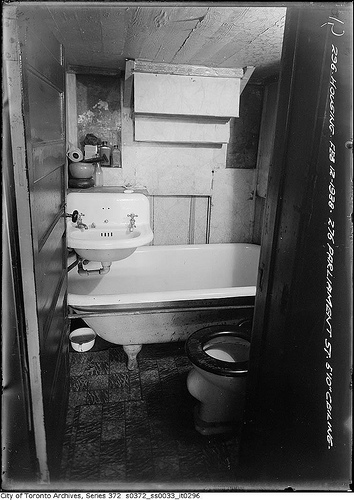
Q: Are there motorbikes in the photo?
A: No, there are no motorbikes.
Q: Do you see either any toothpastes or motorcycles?
A: No, there are no motorcycles or toothpastes.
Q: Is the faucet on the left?
A: Yes, the faucet is on the left of the image.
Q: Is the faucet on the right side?
A: No, the faucet is on the left of the image.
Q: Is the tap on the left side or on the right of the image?
A: The tap is on the left of the image.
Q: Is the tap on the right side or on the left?
A: The tap is on the left of the image.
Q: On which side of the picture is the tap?
A: The tap is on the left of the image.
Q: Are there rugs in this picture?
A: No, there are no rugs.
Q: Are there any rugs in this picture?
A: No, there are no rugs.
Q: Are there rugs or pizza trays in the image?
A: No, there are no rugs or pizza trays.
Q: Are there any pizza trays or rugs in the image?
A: No, there are no rugs or pizza trays.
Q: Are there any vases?
A: No, there are no vases.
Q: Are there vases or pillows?
A: No, there are no vases or pillows.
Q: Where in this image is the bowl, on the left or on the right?
A: The bowl is on the left of the image.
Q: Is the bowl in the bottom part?
A: Yes, the bowl is in the bottom of the image.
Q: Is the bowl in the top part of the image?
A: No, the bowl is in the bottom of the image.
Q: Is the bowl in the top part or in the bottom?
A: The bowl is in the bottom of the image.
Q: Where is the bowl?
A: The bowl is on the floor.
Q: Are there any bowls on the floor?
A: Yes, there is a bowl on the floor.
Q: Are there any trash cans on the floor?
A: No, there is a bowl on the floor.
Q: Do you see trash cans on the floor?
A: No, there is a bowl on the floor.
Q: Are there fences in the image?
A: No, there are no fences.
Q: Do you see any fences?
A: No, there are no fences.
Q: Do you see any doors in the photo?
A: Yes, there is a door.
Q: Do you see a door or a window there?
A: Yes, there is a door.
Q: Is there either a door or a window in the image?
A: Yes, there is a door.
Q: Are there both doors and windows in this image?
A: No, there is a door but no windows.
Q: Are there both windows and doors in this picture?
A: No, there is a door but no windows.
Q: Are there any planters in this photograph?
A: No, there are no planters.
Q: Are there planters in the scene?
A: No, there are no planters.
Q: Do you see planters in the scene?
A: No, there are no planters.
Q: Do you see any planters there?
A: No, there are no planters.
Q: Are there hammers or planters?
A: No, there are no planters or hammers.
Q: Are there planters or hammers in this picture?
A: No, there are no planters or hammers.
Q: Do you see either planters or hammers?
A: No, there are no planters or hammers.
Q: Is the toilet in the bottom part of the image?
A: Yes, the toilet is in the bottom of the image.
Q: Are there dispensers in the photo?
A: No, there are no dispensers.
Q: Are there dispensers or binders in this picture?
A: No, there are no dispensers or binders.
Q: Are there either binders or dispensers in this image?
A: No, there are no dispensers or binders.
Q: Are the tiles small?
A: Yes, the tiles are small.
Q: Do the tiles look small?
A: Yes, the tiles are small.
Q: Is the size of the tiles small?
A: Yes, the tiles are small.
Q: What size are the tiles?
A: The tiles are small.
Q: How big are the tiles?
A: The tiles are small.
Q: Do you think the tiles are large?
A: No, the tiles are small.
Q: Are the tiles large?
A: No, the tiles are small.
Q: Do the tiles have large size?
A: No, the tiles are small.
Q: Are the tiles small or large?
A: The tiles are small.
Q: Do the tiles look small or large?
A: The tiles are small.